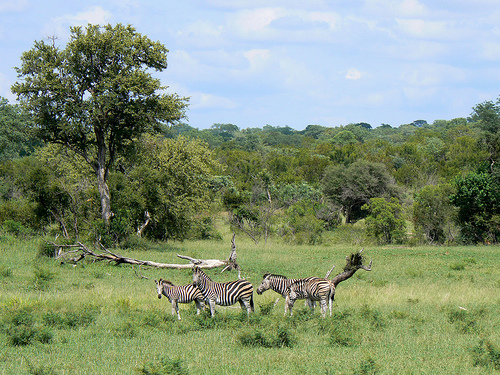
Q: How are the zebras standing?
A: In a line.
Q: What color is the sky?
A: Blue.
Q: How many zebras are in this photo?
A: Four.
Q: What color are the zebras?
A: Black and white.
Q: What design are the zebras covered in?
A: Stripes.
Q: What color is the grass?
A: Green.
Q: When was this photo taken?
A: Outside, during the daytime.